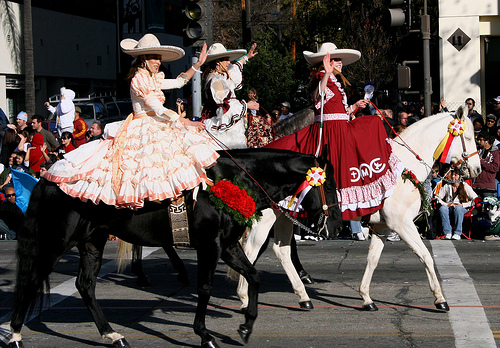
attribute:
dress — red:
[254, 52, 417, 224]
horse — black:
[8, 143, 342, 346]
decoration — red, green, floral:
[202, 177, 268, 231]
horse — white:
[21, 116, 380, 346]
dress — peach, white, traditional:
[40, 70, 218, 211]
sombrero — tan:
[117, 31, 184, 62]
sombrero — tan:
[199, 42, 247, 64]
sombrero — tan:
[300, 41, 362, 65]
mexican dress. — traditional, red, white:
[262, 71, 402, 218]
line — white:
[425, 239, 497, 345]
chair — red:
[431, 173, 481, 241]